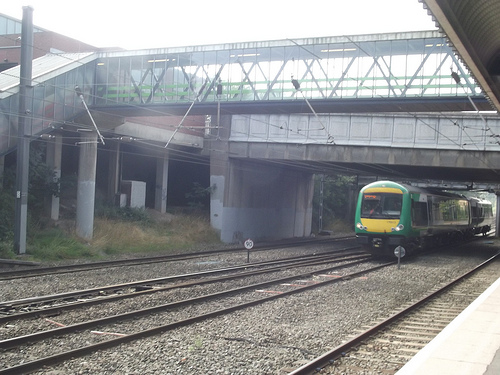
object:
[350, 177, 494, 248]
train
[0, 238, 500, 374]
tracks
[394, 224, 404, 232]
headlights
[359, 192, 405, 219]
windshield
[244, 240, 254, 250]
black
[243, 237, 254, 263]
sign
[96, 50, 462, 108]
walkway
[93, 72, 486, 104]
railing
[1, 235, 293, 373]
three of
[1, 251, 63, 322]
two of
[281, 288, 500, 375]
one of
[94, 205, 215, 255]
hillside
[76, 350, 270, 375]
gravel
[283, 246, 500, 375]
fourth tracks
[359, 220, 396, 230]
yellow and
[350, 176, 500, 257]
two train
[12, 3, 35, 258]
metal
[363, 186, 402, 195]
yellow and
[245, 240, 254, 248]
black lettering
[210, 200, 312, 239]
gray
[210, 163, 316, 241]
wall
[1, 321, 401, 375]
two rails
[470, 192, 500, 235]
second car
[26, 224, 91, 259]
ground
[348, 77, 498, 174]
hanging wires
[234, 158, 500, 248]
tunnel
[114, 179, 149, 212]
electrical box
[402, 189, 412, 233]
green and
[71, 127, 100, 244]
pillars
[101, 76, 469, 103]
people walking